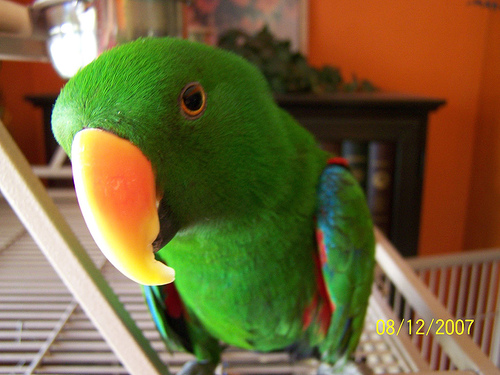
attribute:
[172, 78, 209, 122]
eye — black middle., yellow, round, 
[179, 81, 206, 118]
eye — yellow, black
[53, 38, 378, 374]
parrot — staring, green,  mostly green.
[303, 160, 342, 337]
vibrant coloring — red, blue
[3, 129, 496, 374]
bird cage — open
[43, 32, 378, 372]
bird — colorful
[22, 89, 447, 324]
furniture — dark brown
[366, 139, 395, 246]
book — Three.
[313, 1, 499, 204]
wall — behind, orange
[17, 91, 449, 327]
bookshelf — brown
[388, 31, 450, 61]
wall — orange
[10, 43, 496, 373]
parrot — blue, red, green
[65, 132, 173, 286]
beak — yellow , large 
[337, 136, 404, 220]
book — row, several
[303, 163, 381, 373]
wing — red edging., blue, green 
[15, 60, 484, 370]
birdcage — opened, birds 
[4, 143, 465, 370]
surface. —  multi level white 